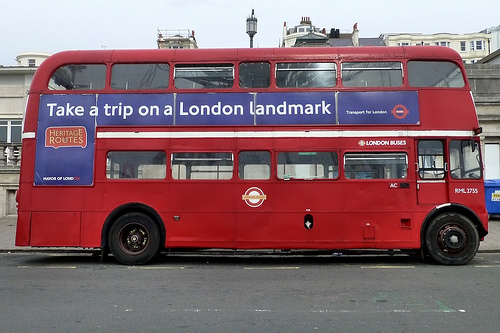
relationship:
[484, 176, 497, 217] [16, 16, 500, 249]
garbage bin by building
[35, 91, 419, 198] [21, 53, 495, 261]
advertisement on bus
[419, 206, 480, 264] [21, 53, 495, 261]
wheel on bus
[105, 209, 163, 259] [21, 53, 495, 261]
wheel on bus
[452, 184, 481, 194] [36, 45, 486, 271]
serial number on bus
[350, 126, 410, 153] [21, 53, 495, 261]
bus company written on bus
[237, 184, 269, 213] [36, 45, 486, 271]
emblem on middle of bus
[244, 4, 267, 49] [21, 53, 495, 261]
light post behind bus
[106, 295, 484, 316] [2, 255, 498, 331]
markings on road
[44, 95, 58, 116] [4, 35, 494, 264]
letter on bus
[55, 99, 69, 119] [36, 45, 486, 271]
letter on bus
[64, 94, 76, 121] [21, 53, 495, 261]
letter on bus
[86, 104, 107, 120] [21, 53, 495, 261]
letter on bus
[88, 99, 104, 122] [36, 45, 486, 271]
letter on bus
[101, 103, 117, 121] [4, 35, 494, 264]
letter on bus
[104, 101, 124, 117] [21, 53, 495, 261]
letter on bus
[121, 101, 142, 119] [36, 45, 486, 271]
letter on bus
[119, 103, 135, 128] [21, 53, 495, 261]
letter on bus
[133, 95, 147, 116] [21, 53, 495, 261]
letter on bus